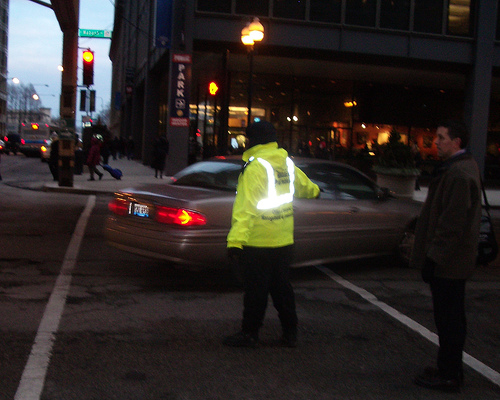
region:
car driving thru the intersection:
[112, 102, 428, 275]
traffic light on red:
[74, 44, 107, 91]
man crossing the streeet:
[214, 104, 309, 352]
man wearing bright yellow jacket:
[203, 114, 318, 351]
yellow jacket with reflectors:
[232, 146, 305, 261]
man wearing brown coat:
[406, 93, 489, 398]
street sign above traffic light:
[76, 19, 114, 43]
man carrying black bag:
[380, 127, 482, 367]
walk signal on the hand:
[198, 71, 232, 101]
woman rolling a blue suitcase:
[81, 125, 118, 182]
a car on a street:
[104, 156, 425, 274]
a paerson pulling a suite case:
[83, 142, 126, 188]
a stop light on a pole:
[74, 46, 96, 96]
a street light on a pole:
[235, 13, 268, 141]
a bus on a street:
[21, 120, 51, 155]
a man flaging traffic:
[218, 122, 324, 352]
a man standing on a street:
[407, 118, 492, 397]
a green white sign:
[75, 25, 102, 40]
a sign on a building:
[172, 51, 192, 136]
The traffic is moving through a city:
[28, 17, 484, 373]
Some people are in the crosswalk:
[17, 22, 489, 383]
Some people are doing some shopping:
[35, 6, 487, 391]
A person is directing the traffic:
[15, 20, 497, 380]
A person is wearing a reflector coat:
[16, 12, 488, 384]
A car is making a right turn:
[36, 23, 496, 380]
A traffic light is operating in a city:
[16, 22, 482, 367]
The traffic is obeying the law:
[5, 15, 486, 370]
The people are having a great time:
[17, 21, 493, 382]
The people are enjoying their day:
[11, 22, 486, 392]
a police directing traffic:
[38, 17, 495, 320]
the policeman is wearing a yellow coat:
[188, 106, 330, 352]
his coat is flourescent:
[235, 156, 310, 231]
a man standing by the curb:
[368, 97, 495, 388]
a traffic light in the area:
[47, 28, 122, 96]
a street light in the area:
[221, 11, 278, 131]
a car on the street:
[109, 138, 448, 283]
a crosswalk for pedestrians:
[25, 180, 447, 392]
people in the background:
[40, 122, 143, 190]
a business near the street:
[161, 75, 435, 164]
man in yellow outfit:
[161, 122, 341, 304]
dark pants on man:
[219, 239, 306, 325]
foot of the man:
[211, 322, 267, 355]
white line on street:
[14, 256, 121, 351]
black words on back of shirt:
[263, 160, 299, 199]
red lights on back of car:
[81, 171, 228, 255]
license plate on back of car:
[119, 194, 164, 229]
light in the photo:
[60, 31, 118, 96]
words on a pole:
[153, 47, 210, 130]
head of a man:
[411, 116, 475, 168]